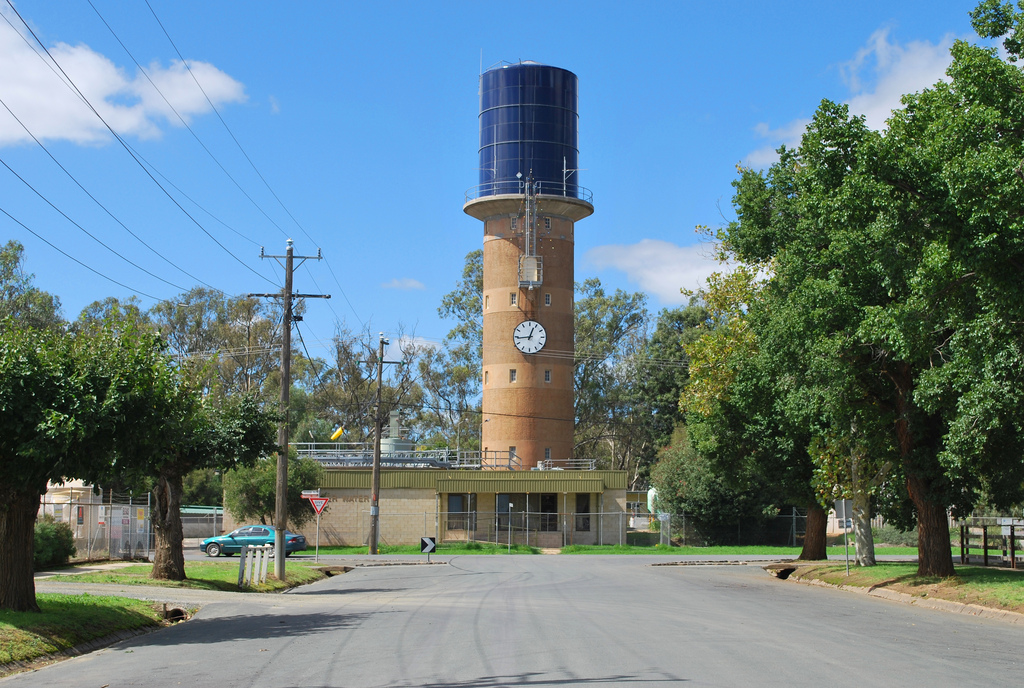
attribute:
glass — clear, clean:
[531, 354, 555, 384]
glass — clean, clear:
[452, 493, 466, 531]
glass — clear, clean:
[495, 493, 541, 516]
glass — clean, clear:
[527, 498, 559, 531]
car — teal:
[182, 509, 344, 566]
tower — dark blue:
[467, 66, 597, 202]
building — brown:
[215, 66, 650, 537]